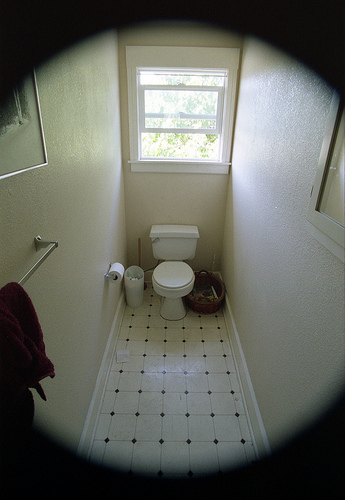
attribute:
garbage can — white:
[123, 264, 145, 307]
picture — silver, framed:
[0, 98, 97, 202]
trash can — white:
[123, 263, 145, 307]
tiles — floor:
[136, 361, 266, 431]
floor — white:
[84, 279, 263, 478]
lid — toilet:
[149, 257, 194, 291]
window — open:
[136, 65, 225, 157]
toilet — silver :
[148, 223, 201, 321]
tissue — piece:
[112, 341, 135, 366]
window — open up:
[132, 65, 234, 172]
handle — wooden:
[132, 236, 139, 260]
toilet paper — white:
[116, 348, 131, 362]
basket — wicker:
[177, 266, 231, 314]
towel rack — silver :
[12, 237, 67, 295]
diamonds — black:
[145, 346, 199, 387]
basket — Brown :
[180, 269, 226, 313]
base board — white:
[80, 273, 264, 433]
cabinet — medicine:
[278, 118, 344, 222]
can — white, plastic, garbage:
[126, 260, 154, 301]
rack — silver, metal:
[20, 240, 66, 283]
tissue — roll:
[95, 252, 131, 285]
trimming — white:
[127, 48, 241, 176]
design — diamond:
[153, 363, 205, 449]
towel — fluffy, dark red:
[2, 279, 54, 445]